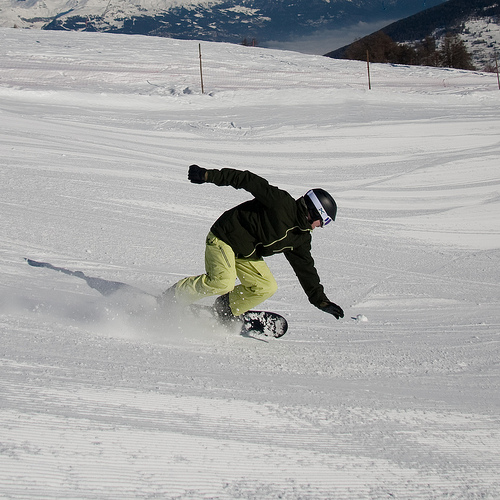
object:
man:
[152, 164, 344, 337]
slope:
[3, 31, 499, 499]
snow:
[0, 0, 499, 500]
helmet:
[303, 187, 337, 227]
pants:
[172, 230, 278, 320]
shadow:
[24, 256, 158, 307]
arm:
[283, 246, 325, 304]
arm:
[207, 168, 278, 205]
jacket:
[206, 167, 326, 306]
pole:
[198, 43, 204, 94]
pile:
[156, 84, 203, 99]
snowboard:
[188, 302, 287, 343]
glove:
[187, 164, 207, 185]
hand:
[187, 164, 208, 184]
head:
[298, 187, 338, 231]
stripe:
[306, 191, 327, 221]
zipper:
[218, 245, 232, 268]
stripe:
[243, 225, 299, 259]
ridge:
[388, 0, 452, 27]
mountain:
[321, 0, 500, 71]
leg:
[170, 232, 237, 303]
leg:
[226, 255, 278, 316]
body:
[172, 193, 302, 317]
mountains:
[0, 1, 444, 57]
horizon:
[0, 23, 495, 37]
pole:
[365, 48, 371, 90]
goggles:
[306, 189, 333, 229]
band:
[307, 189, 328, 218]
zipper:
[273, 246, 294, 253]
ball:
[356, 312, 368, 322]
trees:
[343, 34, 477, 72]